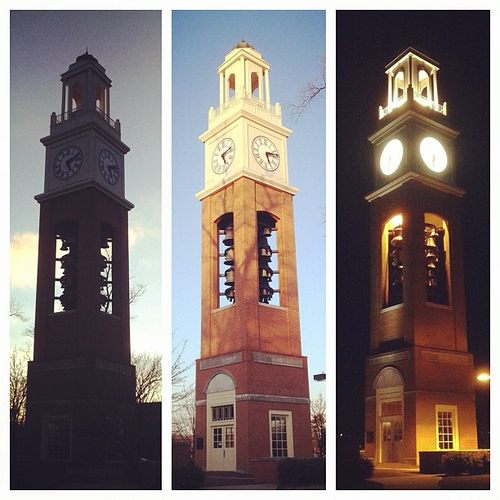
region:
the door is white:
[188, 398, 256, 482]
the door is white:
[216, 390, 252, 478]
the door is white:
[200, 424, 281, 494]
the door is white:
[188, 381, 298, 496]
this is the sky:
[175, 106, 197, 189]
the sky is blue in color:
[171, 110, 197, 187]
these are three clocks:
[54, 139, 462, 182]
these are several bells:
[219, 220, 284, 302]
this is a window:
[270, 416, 290, 456]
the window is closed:
[271, 419, 291, 456]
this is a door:
[202, 390, 242, 472]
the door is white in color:
[208, 450, 234, 467]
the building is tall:
[198, 35, 305, 473]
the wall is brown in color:
[214, 330, 258, 347]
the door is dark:
[47, 394, 129, 481]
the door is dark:
[83, 380, 140, 462]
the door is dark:
[30, 412, 170, 474]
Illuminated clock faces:
[369, 126, 454, 185]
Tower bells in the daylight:
[205, 198, 295, 316]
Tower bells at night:
[376, 206, 454, 326]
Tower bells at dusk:
[39, 216, 133, 318]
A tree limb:
[297, 56, 336, 136]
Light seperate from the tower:
[473, 357, 497, 393]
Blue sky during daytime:
[187, 26, 201, 67]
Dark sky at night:
[350, 22, 370, 67]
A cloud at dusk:
[12, 215, 34, 281]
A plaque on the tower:
[362, 424, 379, 451]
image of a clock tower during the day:
[176, 10, 322, 475]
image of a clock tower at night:
[355, 36, 472, 471]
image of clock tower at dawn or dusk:
[25, 40, 140, 457]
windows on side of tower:
[260, 396, 295, 461]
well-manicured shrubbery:
[430, 443, 488, 478]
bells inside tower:
[211, 202, 279, 304]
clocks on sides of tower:
[200, 123, 281, 179]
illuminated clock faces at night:
[333, 126, 483, 181]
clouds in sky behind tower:
[10, 40, 160, 346]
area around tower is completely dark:
[338, 11, 492, 351]